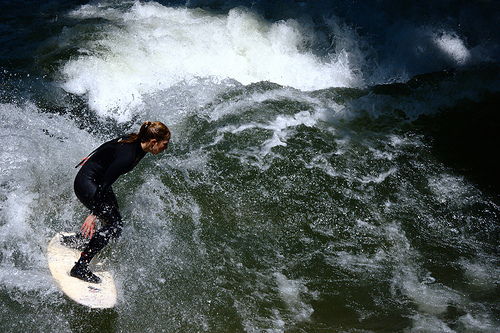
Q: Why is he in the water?
A: Hes surfing.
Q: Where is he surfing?
A: In a big lake.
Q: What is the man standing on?
A: Surfboard.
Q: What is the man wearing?
A: Surf clothes.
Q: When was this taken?
A: Daytime.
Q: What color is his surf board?
A: White.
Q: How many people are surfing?
A: 1.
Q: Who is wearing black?
A: The surfer.